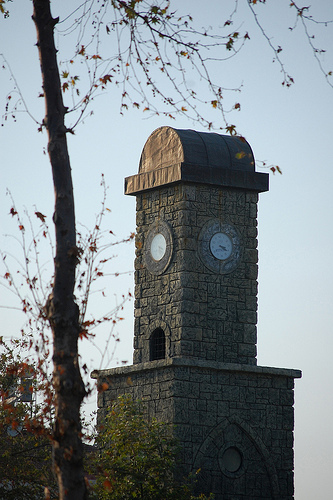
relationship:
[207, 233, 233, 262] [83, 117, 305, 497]
clock in clock tower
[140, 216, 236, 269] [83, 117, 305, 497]
clocks on clock tower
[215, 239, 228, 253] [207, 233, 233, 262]
hands on clock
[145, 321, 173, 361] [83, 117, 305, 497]
door on clock tower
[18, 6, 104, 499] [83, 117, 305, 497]
tree next to clock tower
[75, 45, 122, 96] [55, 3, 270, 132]
leaves on branches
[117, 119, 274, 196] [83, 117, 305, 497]
dome of clock tower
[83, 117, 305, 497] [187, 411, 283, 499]
clock tower has arch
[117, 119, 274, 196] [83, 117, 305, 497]
dome on clock tower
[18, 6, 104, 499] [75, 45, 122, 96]
tree has leaves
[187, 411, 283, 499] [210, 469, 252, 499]
arch has gate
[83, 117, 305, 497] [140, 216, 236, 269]
clock tower has clocks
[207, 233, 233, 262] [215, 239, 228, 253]
clock has hands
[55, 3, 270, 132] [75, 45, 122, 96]
branches with leaves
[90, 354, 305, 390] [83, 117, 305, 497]
ledge around clock tower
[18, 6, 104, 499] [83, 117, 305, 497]
tree in front of clock tower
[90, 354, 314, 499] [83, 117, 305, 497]
base of clock tower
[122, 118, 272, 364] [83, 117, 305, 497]
top of clock tower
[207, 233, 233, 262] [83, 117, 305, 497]
clock on clock tower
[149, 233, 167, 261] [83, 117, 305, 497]
clocks on clock tower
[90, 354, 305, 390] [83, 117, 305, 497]
ledge on clock tower